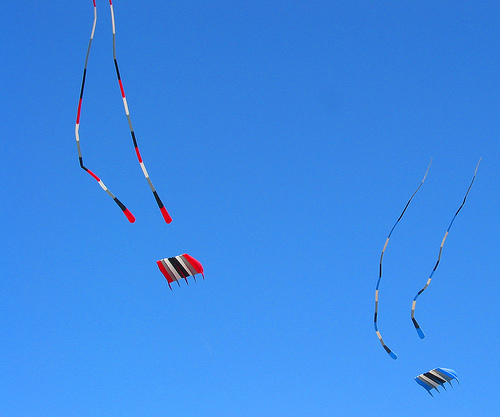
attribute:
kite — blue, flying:
[374, 155, 481, 397]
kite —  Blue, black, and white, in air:
[347, 144, 498, 404]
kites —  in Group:
[371, 156, 492, 401]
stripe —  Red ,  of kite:
[182, 252, 206, 272]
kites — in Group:
[146, 245, 229, 303]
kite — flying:
[67, 39, 242, 310]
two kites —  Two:
[62, 8, 485, 401]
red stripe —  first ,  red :
[153, 205, 179, 226]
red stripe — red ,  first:
[119, 202, 138, 226]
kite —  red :
[67, 0, 179, 228]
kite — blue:
[361, 151, 483, 401]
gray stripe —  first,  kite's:
[101, 186, 116, 198]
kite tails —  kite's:
[70, 0, 207, 289]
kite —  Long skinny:
[54, 0, 206, 293]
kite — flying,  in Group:
[70, 9, 210, 295]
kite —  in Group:
[52, 3, 239, 315]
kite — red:
[148, 246, 213, 288]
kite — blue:
[329, 280, 466, 397]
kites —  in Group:
[373, 155, 482, 397]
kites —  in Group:
[74, 5, 204, 291]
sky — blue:
[1, 2, 498, 413]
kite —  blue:
[371, 307, 458, 379]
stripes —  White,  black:
[161, 254, 192, 278]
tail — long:
[371, 157, 481, 360]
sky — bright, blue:
[166, 9, 392, 171]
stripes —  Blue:
[432, 366, 462, 383]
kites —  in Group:
[74, 2, 484, 397]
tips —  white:
[412, 145, 494, 185]